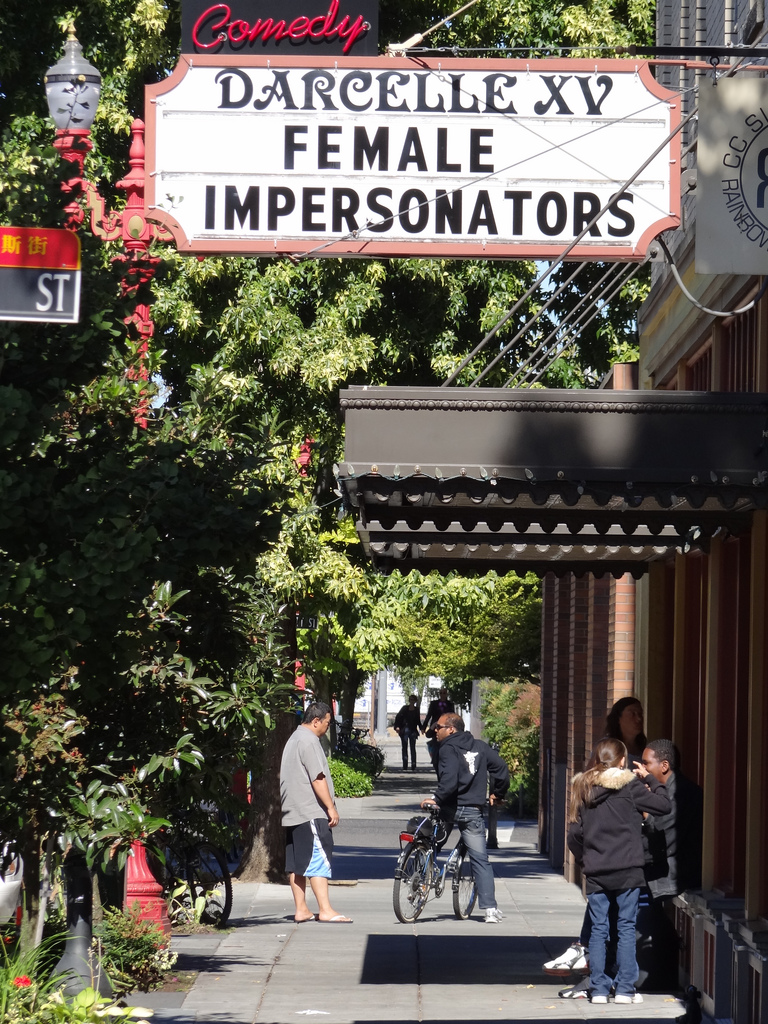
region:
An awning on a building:
[333, 373, 766, 578]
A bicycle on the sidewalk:
[393, 796, 484, 926]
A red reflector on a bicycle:
[394, 825, 421, 844]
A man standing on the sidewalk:
[271, 700, 359, 927]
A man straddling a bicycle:
[418, 708, 510, 928]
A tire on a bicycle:
[392, 840, 426, 926]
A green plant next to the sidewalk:
[96, 899, 161, 994]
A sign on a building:
[140, 45, 689, 271]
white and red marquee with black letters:
[136, 39, 695, 271]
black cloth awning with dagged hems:
[320, 371, 765, 577]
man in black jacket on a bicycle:
[379, 711, 519, 932]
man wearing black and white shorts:
[274, 689, 359, 925]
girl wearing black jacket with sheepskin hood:
[555, 733, 673, 1009]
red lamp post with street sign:
[2, 37, 179, 956]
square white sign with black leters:
[682, 53, 758, 283]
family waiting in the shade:
[539, 693, 688, 1008]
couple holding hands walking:
[386, 682, 454, 769]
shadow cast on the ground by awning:
[346, 917, 585, 993]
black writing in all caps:
[201, 176, 647, 236]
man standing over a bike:
[377, 697, 516, 930]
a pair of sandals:
[289, 908, 364, 929]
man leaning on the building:
[547, 736, 688, 1008]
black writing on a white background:
[135, 48, 694, 250]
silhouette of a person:
[394, 688, 430, 770]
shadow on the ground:
[354, 922, 601, 982]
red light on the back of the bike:
[393, 828, 419, 844]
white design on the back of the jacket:
[458, 739, 482, 775]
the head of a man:
[291, 694, 345, 744]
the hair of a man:
[294, 677, 364, 769]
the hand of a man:
[307, 795, 370, 836]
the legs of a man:
[276, 826, 376, 926]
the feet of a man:
[265, 868, 387, 975]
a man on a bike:
[366, 686, 554, 958]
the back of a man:
[252, 714, 317, 825]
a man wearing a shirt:
[254, 686, 398, 835]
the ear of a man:
[302, 703, 339, 742]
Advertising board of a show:
[141, 3, 677, 257]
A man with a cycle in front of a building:
[391, 710, 506, 925]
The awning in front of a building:
[339, 388, 766, 567]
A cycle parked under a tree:
[161, 837, 232, 928]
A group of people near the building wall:
[542, 696, 689, 1006]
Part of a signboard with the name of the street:
[1, 228, 81, 328]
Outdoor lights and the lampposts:
[41, 14, 170, 437]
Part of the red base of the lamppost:
[121, 832, 167, 954]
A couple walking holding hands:
[391, 688, 451, 771]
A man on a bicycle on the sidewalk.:
[377, 689, 531, 943]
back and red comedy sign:
[170, 3, 387, 52]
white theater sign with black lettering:
[132, 51, 687, 274]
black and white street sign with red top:
[2, 217, 88, 323]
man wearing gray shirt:
[268, 702, 351, 923]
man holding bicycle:
[421, 689, 527, 912]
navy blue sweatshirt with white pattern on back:
[427, 739, 509, 809]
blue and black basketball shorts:
[277, 807, 339, 881]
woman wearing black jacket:
[562, 742, 660, 1000]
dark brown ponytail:
[567, 738, 627, 789]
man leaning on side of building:
[532, 710, 695, 979]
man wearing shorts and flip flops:
[279, 688, 343, 951]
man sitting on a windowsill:
[648, 742, 692, 910]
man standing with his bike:
[400, 713, 502, 926]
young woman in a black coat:
[579, 731, 639, 1015]